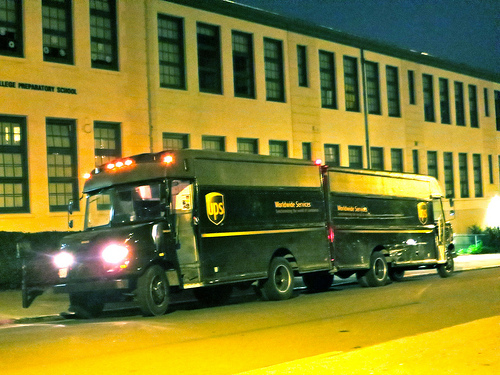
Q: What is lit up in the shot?
A: The road.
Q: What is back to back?
A: The two trucks.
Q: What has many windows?
A: The building.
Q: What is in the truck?
A: No one is in the truck.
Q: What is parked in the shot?
A: The trucks.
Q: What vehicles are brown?
A: The trucks.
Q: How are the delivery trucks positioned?
A: Back to back.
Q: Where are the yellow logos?
A: On the sides of the trucks.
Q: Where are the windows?
A: On the building.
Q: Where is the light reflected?
A: On the pavement.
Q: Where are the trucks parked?
A: On the street.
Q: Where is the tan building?
A: Behind the trucks.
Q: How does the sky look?
A: Dark.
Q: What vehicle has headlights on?
A: The UPS truck.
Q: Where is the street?
A: Under the trucks.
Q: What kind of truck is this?
A: A ups truck.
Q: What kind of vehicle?
A: A truck.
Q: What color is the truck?
A: Brown.